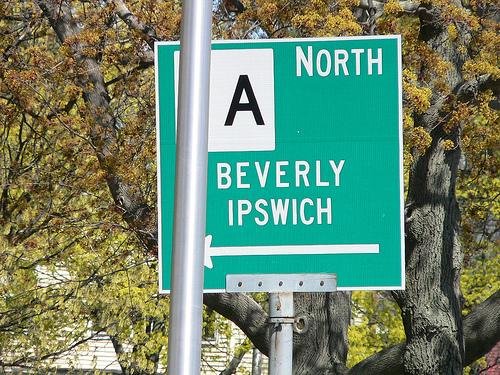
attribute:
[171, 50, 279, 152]
box — white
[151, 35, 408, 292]
sign — green, white, bolted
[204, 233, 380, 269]
arrow — white, pointing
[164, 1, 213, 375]
pole — steel, metal, silver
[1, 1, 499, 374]
tree — thick, green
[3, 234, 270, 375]
building — white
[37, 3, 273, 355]
branch — large, brown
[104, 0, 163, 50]
branch — brown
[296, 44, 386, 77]
north — white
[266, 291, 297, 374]
pole — metal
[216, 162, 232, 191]
letter — white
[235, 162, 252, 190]
letter — white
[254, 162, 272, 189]
letter — white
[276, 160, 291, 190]
letter — white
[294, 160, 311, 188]
letter — white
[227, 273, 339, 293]
bracket — metal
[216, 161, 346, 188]
name — white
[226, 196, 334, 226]
name — white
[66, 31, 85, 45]
leaf — orange